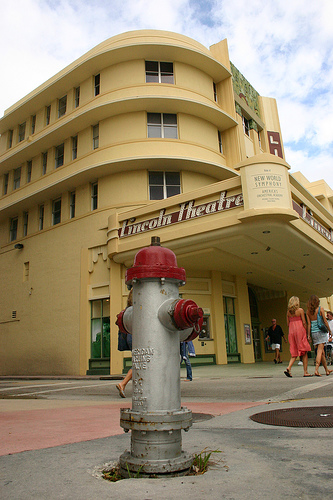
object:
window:
[146, 168, 183, 200]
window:
[145, 110, 179, 138]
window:
[145, 59, 176, 83]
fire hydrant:
[115, 243, 203, 477]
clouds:
[1, 2, 332, 31]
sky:
[2, 0, 332, 184]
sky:
[1, 2, 330, 180]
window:
[71, 134, 78, 159]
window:
[70, 185, 75, 220]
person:
[180, 339, 200, 382]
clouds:
[1, 2, 332, 180]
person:
[306, 291, 332, 380]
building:
[0, 29, 332, 378]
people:
[285, 294, 332, 379]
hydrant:
[115, 234, 205, 477]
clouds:
[0, 0, 332, 184]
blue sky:
[0, 0, 332, 185]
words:
[119, 190, 244, 238]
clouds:
[1, 1, 332, 149]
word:
[120, 192, 241, 237]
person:
[268, 294, 331, 378]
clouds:
[233, 0, 331, 182]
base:
[103, 418, 210, 476]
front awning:
[107, 152, 332, 295]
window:
[91, 121, 100, 150]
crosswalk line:
[258, 379, 332, 401]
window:
[91, 68, 102, 97]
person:
[266, 318, 285, 364]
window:
[74, 85, 81, 108]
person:
[284, 290, 309, 379]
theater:
[0, 29, 330, 380]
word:
[114, 191, 247, 240]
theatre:
[1, 28, 332, 377]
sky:
[2, 2, 331, 170]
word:
[130, 345, 155, 370]